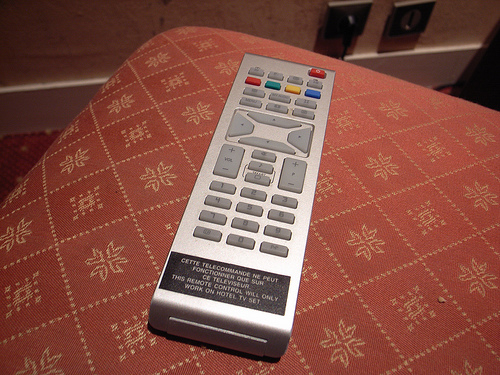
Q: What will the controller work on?
A: Hotel TV set.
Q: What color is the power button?
A: Red.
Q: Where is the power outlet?
A: Top right side of photo.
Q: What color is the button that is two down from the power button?
A: Blue.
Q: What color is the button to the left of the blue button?
A: Yellow.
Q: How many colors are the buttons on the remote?
A: Five.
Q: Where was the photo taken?
A: In the living room.